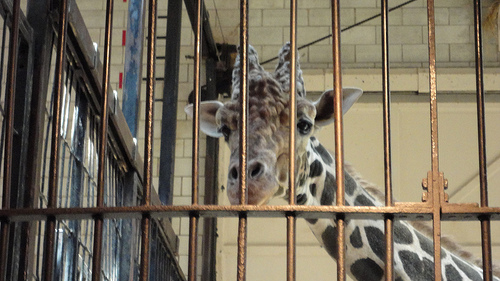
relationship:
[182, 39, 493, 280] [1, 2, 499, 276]
giraffe behind cage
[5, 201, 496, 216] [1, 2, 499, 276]
bar of cage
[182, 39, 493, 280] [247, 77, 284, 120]
giraffe has brown spots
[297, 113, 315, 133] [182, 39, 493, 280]
eye of giraffe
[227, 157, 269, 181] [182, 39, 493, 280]
nose of giraffe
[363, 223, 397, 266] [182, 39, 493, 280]
black spot on giraffe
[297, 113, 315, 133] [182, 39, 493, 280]
eye on giraffe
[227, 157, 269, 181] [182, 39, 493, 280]
nose on giraffe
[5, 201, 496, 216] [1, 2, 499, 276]
bar on cage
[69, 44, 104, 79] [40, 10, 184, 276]
hinges are on fence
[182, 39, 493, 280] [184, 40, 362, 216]
giraffe has head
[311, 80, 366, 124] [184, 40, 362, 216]
ear on head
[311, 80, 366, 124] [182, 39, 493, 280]
ear on giraffe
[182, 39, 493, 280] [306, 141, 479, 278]
giraffe has long neck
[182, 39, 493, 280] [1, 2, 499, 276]
giraffe in cage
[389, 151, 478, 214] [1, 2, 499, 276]
bracket connects cage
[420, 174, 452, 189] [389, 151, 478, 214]
metal bolts attach bracket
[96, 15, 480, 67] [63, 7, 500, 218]
cinderblock wall in background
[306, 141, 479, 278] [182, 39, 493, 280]
long neck on giraffe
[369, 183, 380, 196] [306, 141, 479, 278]
brown hairs are on mane